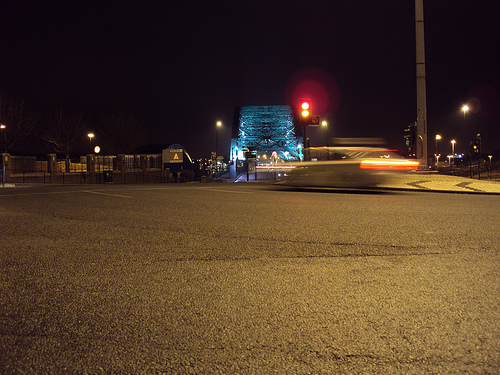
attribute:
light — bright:
[289, 88, 321, 135]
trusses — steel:
[228, 93, 310, 168]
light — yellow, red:
[302, 96, 324, 133]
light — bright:
[315, 117, 329, 131]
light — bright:
[298, 93, 319, 129]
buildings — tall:
[196, 151, 226, 180]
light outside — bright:
[209, 118, 238, 135]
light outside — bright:
[70, 122, 100, 146]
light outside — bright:
[436, 99, 475, 132]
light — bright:
[301, 101, 308, 108]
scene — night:
[29, 22, 489, 346]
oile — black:
[300, 117, 307, 158]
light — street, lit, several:
[457, 99, 472, 119]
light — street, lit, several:
[448, 133, 460, 150]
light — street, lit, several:
[434, 127, 443, 146]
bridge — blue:
[227, 98, 331, 186]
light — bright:
[300, 98, 310, 118]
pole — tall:
[401, 1, 443, 173]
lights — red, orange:
[287, 96, 324, 124]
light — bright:
[300, 97, 310, 114]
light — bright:
[298, 106, 318, 125]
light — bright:
[457, 99, 474, 118]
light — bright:
[315, 116, 333, 133]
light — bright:
[213, 117, 229, 132]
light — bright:
[83, 122, 103, 142]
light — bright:
[297, 92, 312, 114]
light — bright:
[295, 106, 313, 117]